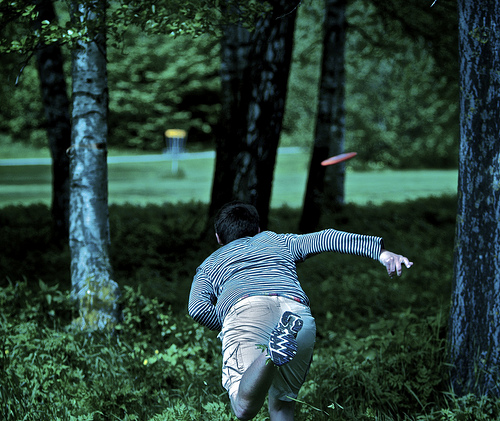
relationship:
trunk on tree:
[69, 8, 124, 329] [0, 1, 277, 331]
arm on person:
[302, 224, 374, 267] [206, 204, 269, 299]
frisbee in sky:
[320, 151, 355, 166] [75, 51, 260, 159]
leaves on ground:
[6, 278, 221, 419] [7, 198, 458, 419]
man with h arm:
[167, 194, 452, 419] [279, 227, 381, 263]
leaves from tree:
[0, 0, 275, 57] [66, 0, 123, 341]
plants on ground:
[132, 250, 161, 355] [2, 147, 497, 417]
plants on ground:
[53, 354, 141, 398] [141, 305, 428, 380]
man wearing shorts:
[197, 194, 293, 285] [215, 299, 283, 365]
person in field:
[184, 200, 419, 420] [2, 147, 499, 418]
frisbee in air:
[320, 150, 358, 166] [67, 103, 347, 154]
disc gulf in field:
[165, 128, 185, 180] [108, 148, 213, 203]